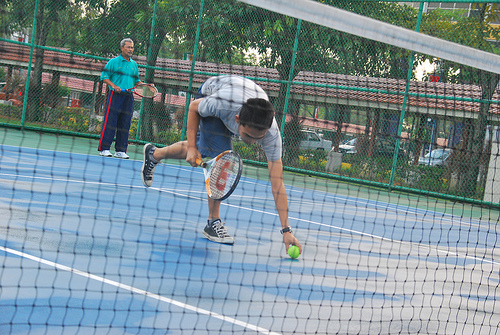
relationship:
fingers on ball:
[281, 231, 307, 269] [285, 245, 310, 261]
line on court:
[24, 255, 187, 312] [39, 156, 446, 334]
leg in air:
[118, 131, 210, 177] [103, 97, 193, 230]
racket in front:
[183, 116, 248, 222] [133, 149, 325, 258]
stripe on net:
[242, 0, 499, 79] [1, 14, 486, 334]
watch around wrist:
[275, 224, 302, 239] [272, 221, 305, 243]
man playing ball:
[120, 49, 339, 286] [288, 245, 300, 258]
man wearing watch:
[120, 49, 339, 286] [275, 224, 302, 239]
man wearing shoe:
[120, 49, 339, 286] [201, 206, 245, 249]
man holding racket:
[120, 49, 339, 286] [183, 116, 248, 222]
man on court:
[120, 49, 339, 286] [39, 156, 446, 334]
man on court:
[140, 74, 302, 261] [39, 156, 446, 334]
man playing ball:
[140, 74, 302, 261] [288, 245, 300, 258]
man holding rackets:
[140, 74, 302, 261] [123, 65, 246, 208]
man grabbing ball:
[120, 49, 339, 286] [285, 245, 310, 261]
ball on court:
[285, 245, 310, 261] [39, 156, 446, 334]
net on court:
[1, 14, 486, 334] [39, 156, 446, 334]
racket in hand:
[183, 116, 248, 222] [177, 136, 207, 175]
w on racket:
[211, 150, 234, 194] [183, 116, 248, 222]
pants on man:
[71, 81, 161, 160] [93, 12, 146, 157]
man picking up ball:
[140, 74, 302, 261] [285, 245, 310, 261]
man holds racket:
[93, 12, 146, 157] [126, 72, 170, 112]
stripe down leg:
[91, 87, 115, 152] [96, 88, 121, 150]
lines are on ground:
[39, 156, 446, 334] [1, 121, 484, 331]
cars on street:
[3, 86, 490, 172] [290, 142, 476, 191]